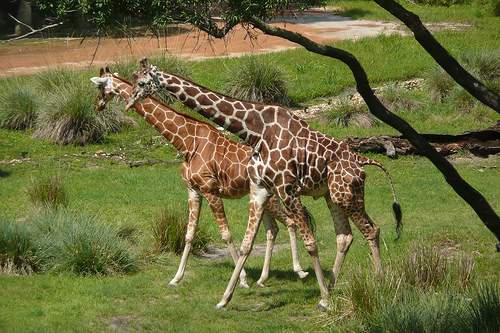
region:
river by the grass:
[22, 5, 462, 65]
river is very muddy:
[39, 3, 374, 68]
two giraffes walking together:
[59, 50, 401, 321]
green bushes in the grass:
[6, 163, 177, 308]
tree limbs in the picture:
[275, 46, 496, 248]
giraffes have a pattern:
[223, 98, 305, 163]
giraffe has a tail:
[356, 152, 420, 242]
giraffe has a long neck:
[124, 66, 290, 147]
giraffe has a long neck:
[89, 66, 193, 200]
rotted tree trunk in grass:
[337, 132, 497, 169]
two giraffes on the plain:
[86, 53, 406, 316]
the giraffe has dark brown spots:
[120, 58, 406, 313]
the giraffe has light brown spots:
[86, 62, 311, 312]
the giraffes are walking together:
[86, 53, 411, 319]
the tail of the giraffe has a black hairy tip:
[365, 155, 406, 243]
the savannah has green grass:
[11, 45, 492, 330]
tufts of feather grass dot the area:
[6, 66, 111, 147]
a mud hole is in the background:
[1, 20, 451, 70]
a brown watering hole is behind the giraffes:
[2, 8, 498, 67]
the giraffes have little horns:
[91, 56, 155, 81]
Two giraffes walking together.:
[32, 40, 415, 314]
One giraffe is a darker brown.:
[114, 41, 421, 314]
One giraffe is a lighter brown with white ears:
[39, 48, 330, 318]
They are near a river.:
[6, 23, 237, 77]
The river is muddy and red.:
[6, 18, 356, 70]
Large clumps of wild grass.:
[2, 150, 150, 307]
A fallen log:
[313, 84, 495, 189]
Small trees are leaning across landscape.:
[148, 12, 498, 247]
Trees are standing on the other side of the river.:
[3, 4, 298, 35]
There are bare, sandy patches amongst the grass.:
[66, 198, 418, 330]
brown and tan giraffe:
[130, 42, 410, 323]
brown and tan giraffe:
[78, 56, 263, 311]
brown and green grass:
[348, 230, 475, 325]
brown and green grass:
[14, 235, 161, 330]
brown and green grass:
[4, 147, 160, 286]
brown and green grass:
[5, 54, 81, 160]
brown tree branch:
[384, 9, 494, 115]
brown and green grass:
[195, 4, 442, 88]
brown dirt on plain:
[13, 20, 184, 57]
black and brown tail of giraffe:
[366, 155, 413, 229]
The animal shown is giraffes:
[88, 56, 403, 314]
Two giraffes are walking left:
[91, 54, 404, 309]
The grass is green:
[1, 0, 499, 332]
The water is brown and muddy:
[0, 9, 468, 74]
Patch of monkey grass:
[2, 55, 184, 144]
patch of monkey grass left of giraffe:
[1, 176, 206, 279]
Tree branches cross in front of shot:
[33, 1, 498, 259]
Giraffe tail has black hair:
[348, 151, 410, 247]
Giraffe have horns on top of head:
[95, 51, 162, 127]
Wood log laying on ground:
[328, 119, 498, 156]